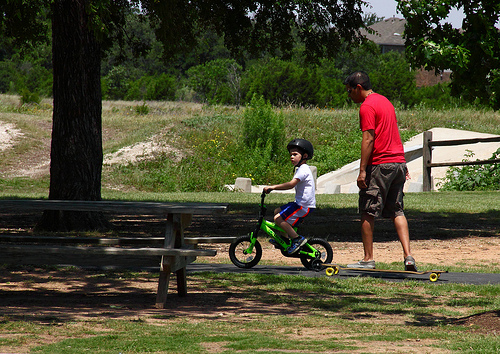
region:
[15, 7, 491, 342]
A outdoors picture.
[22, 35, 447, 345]
Picture taken during the day.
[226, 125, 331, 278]
A boy riding a bike.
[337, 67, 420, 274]
A man standing behind the boy.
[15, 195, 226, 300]
A brown picnic table.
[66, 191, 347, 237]
Shadows of the tree.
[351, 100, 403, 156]
The man wears a red shirt.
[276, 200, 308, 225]
The boy wears shorts.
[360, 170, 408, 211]
The man wears shorts.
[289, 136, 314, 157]
The boy wears a helmet.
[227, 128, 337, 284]
A young boy riding a bike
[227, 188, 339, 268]
The boy's bike is green and black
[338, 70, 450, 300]
The man is riding a skateboard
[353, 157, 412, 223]
The man is wearing gray shorts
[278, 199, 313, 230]
The boy is wearing blue and red shorts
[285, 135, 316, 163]
The boy is wearing a black helmet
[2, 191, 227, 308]
The bench in the park is gray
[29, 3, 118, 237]
The tree trunk is big and brown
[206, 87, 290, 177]
The bush has green leaves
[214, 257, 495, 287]
The bike trail is ashpalt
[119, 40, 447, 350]
two people at a park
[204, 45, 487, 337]
two people on a sidewalk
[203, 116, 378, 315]
a boy riding a bike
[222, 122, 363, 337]
a young boy riding a bike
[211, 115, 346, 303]
a child riding a bike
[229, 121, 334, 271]
a boy wearing a helmet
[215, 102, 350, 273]
a boy wearing a black helmet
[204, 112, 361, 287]
a boy on a green bike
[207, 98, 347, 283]
a young boy on a green bike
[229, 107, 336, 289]
a green bike on the sidewalk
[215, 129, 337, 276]
a child riding a bicycle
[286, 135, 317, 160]
a black helmet on the child's head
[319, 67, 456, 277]
a man riding a skateboard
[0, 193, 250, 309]
a wooden picnic table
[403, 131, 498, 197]
a wooden fence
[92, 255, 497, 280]
a black paved bicycle path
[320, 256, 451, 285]
a skateboard with yellow wheels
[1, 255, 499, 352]
grass with patches of dirt on the ground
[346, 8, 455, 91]
a building beyond the trees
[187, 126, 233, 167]
yellow wild flowers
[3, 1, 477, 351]
a scene outside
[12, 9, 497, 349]
a scene at the park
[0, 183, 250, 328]
a wooden bench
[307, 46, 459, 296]
a man on a skateboard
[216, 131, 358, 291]
a kid on a bike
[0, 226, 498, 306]
a gray sidewalk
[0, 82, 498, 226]
a small incline in background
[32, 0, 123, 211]
a large tree trunk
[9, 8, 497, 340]
a scene during the day time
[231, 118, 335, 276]
child riding green bike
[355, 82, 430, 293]
man walking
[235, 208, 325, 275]
green bike ridden by child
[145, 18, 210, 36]
green leaves in brown tree